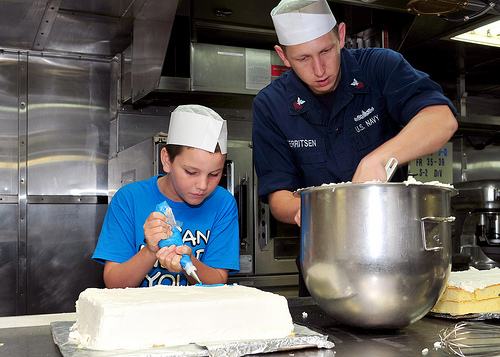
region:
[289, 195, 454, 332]
The big silver mixing bowl the man has his hand in.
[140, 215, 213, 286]
The writing on the boy's t-shirt.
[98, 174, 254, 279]
The blue t-shirt the boy is wearing.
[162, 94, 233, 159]
The white hat on the boy's head.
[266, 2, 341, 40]
The white hat on the man's head.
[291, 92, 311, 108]
The emblem on the man's left collar.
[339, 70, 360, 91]
The emblem on the man's right collar.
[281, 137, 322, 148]
The name on the left side of the man's shirt.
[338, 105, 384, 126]
The words on the right side of the man's shirt.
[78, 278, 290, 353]
The white cake the boy is decorating.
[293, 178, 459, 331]
large silver container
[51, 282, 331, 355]
white cake with white frosting and blue icing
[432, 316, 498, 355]
silver beater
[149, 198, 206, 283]
blue tube of icing in the young man's hand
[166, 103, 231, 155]
white cap on the young man's head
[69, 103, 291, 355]
young man placing icing on a white frosted cake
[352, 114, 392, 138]
white print on the uniform reading U.S. Navy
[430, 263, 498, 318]
cake with white frosting on top of it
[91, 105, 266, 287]
young man wearing a blue t-shirt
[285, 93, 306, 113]
logo on the man's shirt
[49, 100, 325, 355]
a boy applying frosting to a cake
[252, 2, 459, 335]
a young man mixing frosting in a metal bowl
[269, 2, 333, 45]
a chef's hat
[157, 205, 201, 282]
a tube of blue frosting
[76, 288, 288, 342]
a cake sitting on a tinfoil lined platter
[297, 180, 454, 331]
a large metal mixing bowl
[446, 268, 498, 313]
a vanilla cake with white frosting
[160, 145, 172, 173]
a boy's ear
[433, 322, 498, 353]
a wire wisk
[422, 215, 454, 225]
the handle on a metal mixing bowl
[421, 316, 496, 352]
a whisk with a bit of frosting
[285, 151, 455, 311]
hands in a mixing bowl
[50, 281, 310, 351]
cake with white frosting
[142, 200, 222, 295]
frosting being applied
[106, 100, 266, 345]
apprentice chef helps prepare desert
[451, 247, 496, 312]
vanilla layer cake with frosting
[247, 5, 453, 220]
Navy personnel at work in the galley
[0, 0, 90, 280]
rivetted metal sheeting in a ship's kitchen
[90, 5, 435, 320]
man and boy making cake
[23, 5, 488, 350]
working inside a ship's galley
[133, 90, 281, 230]
The kid is wearing a hat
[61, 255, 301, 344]
The cake is white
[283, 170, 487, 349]
The bowl is silver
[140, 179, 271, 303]
The kid is squeezing blue frosting out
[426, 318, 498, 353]
The wisk is metal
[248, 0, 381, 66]
The man has a hat on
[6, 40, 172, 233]
The wall is metal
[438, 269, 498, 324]
The cake is yellow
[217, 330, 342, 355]
The cake is on foil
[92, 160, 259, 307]
The boy has a blue shirt on